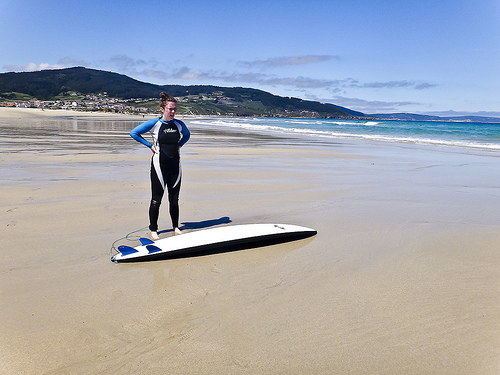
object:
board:
[110, 221, 316, 263]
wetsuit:
[129, 114, 192, 231]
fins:
[112, 242, 138, 254]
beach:
[0, 105, 499, 374]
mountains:
[0, 65, 369, 117]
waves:
[189, 116, 500, 152]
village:
[0, 85, 177, 115]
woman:
[128, 90, 191, 241]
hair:
[156, 91, 177, 112]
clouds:
[0, 54, 441, 91]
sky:
[0, 0, 499, 117]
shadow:
[157, 214, 231, 233]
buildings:
[0, 91, 148, 115]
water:
[0, 113, 341, 155]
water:
[187, 116, 500, 149]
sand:
[0, 106, 499, 373]